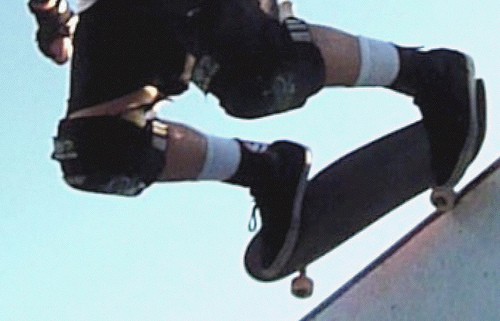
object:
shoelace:
[247, 205, 257, 233]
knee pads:
[57, 14, 328, 197]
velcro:
[279, 14, 329, 105]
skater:
[26, 0, 477, 281]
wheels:
[289, 182, 460, 299]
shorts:
[67, 1, 300, 118]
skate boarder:
[27, 2, 487, 280]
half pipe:
[307, 167, 495, 317]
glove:
[29, 3, 78, 66]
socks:
[200, 36, 401, 182]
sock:
[195, 134, 240, 181]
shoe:
[408, 43, 476, 191]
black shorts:
[61, 1, 328, 120]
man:
[19, 0, 476, 278]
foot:
[256, 140, 313, 277]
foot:
[414, 47, 477, 182]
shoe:
[246, 136, 312, 276]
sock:
[354, 33, 407, 84]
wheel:
[430, 185, 462, 211]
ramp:
[288, 152, 498, 320]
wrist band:
[15, 0, 100, 75]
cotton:
[198, 132, 245, 180]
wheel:
[290, 276, 315, 297]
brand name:
[107, 182, 143, 197]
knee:
[56, 114, 155, 195]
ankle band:
[387, 42, 427, 94]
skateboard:
[240, 77, 490, 303]